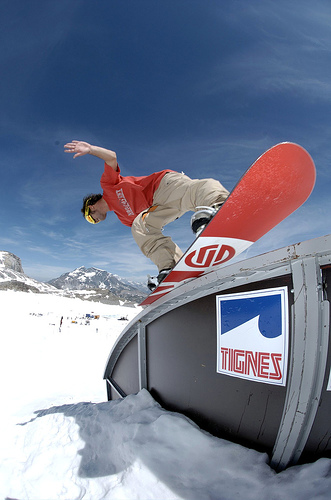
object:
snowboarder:
[63, 139, 232, 290]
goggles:
[85, 192, 95, 224]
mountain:
[0, 247, 22, 279]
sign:
[214, 287, 295, 390]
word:
[221, 346, 286, 380]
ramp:
[103, 234, 330, 472]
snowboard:
[137, 141, 317, 309]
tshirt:
[101, 163, 173, 229]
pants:
[129, 169, 231, 274]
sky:
[1, 0, 330, 289]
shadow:
[17, 386, 328, 499]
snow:
[3, 287, 329, 498]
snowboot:
[188, 199, 229, 235]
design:
[145, 236, 255, 298]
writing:
[115, 185, 136, 218]